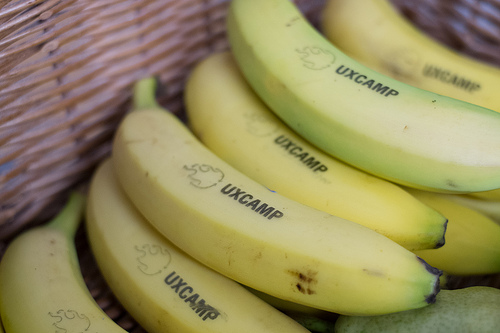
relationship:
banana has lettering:
[144, 136, 375, 272] [222, 176, 285, 230]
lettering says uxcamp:
[222, 176, 285, 230] [338, 67, 397, 103]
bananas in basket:
[112, 44, 435, 294] [1, 22, 165, 100]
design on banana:
[294, 38, 342, 74] [144, 136, 375, 272]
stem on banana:
[128, 74, 163, 109] [144, 136, 375, 272]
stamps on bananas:
[266, 130, 332, 174] [112, 44, 435, 294]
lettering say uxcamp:
[222, 176, 285, 230] [338, 67, 397, 103]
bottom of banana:
[430, 214, 456, 253] [144, 136, 375, 272]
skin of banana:
[160, 240, 325, 257] [144, 136, 375, 272]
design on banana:
[295, 46, 339, 72] [144, 136, 375, 272]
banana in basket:
[144, 136, 375, 272] [1, 22, 165, 100]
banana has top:
[144, 136, 375, 272] [128, 74, 163, 109]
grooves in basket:
[53, 28, 157, 43] [1, 22, 165, 100]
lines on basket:
[38, 31, 169, 63] [1, 22, 165, 100]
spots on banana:
[294, 265, 324, 297] [144, 136, 375, 272]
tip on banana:
[435, 270, 449, 302] [144, 136, 375, 272]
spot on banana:
[406, 84, 453, 109] [144, 136, 375, 272]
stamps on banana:
[273, 134, 330, 174] [144, 136, 375, 272]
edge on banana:
[302, 26, 494, 127] [144, 136, 375, 272]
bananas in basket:
[112, 44, 435, 294] [0, 0, 232, 239]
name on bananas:
[222, 176, 285, 230] [112, 44, 435, 294]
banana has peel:
[144, 136, 375, 272] [350, 118, 474, 160]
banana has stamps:
[144, 136, 375, 272] [266, 130, 332, 174]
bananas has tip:
[112, 44, 435, 294] [435, 270, 449, 302]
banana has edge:
[144, 136, 375, 272] [302, 26, 494, 127]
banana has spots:
[144, 136, 375, 272] [294, 265, 324, 297]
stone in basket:
[384, 293, 500, 321] [1, 22, 165, 100]